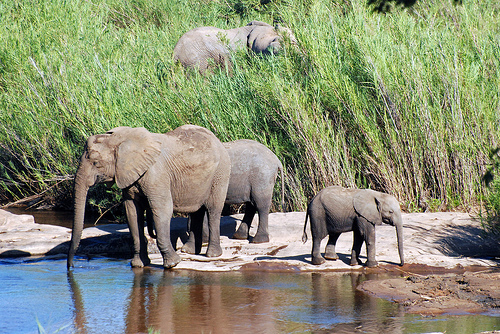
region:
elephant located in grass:
[165, 9, 307, 94]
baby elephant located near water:
[297, 183, 413, 273]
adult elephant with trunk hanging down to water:
[59, 115, 236, 274]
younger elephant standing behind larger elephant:
[176, 133, 291, 259]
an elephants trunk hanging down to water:
[59, 171, 99, 273]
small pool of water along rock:
[4, 263, 399, 330]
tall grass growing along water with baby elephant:
[298, 5, 498, 280]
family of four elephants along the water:
[60, 17, 414, 279]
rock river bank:
[0, 197, 499, 276]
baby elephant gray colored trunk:
[387, 218, 419, 271]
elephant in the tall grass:
[169, 18, 331, 94]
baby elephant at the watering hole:
[299, 150, 410, 271]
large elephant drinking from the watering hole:
[56, 118, 236, 269]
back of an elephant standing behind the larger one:
[214, 135, 281, 242]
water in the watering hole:
[30, 271, 127, 311]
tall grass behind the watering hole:
[339, 48, 445, 143]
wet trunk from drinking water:
[57, 223, 87, 285]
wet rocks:
[256, 240, 292, 257]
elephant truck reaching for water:
[66, 188, 80, 273]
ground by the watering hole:
[413, 219, 458, 259]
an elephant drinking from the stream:
[64, 126, 224, 275]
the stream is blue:
[0, 253, 156, 330]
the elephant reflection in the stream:
[49, 244, 329, 329]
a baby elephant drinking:
[285, 177, 412, 271]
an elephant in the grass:
[165, 11, 300, 74]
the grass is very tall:
[4, 1, 491, 206]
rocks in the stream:
[362, 257, 497, 322]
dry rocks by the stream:
[14, 202, 491, 274]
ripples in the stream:
[227, 275, 423, 327]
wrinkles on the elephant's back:
[152, 140, 190, 212]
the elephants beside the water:
[37, 113, 249, 270]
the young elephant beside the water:
[305, 172, 439, 268]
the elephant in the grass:
[156, 15, 328, 85]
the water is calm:
[34, 268, 281, 323]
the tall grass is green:
[299, 48, 472, 179]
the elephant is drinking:
[55, 107, 227, 269]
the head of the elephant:
[54, 118, 159, 268]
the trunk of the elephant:
[60, 188, 92, 273]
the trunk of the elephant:
[390, 220, 411, 270]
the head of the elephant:
[346, 182, 423, 271]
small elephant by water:
[307, 173, 438, 288]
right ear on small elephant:
[339, 180, 382, 226]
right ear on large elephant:
[111, 131, 152, 184]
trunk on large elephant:
[63, 168, 113, 274]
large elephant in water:
[33, 105, 257, 293]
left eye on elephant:
[88, 145, 103, 170]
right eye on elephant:
[380, 202, 407, 227]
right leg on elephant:
[300, 229, 338, 266]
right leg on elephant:
[359, 232, 382, 271]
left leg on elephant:
[157, 209, 184, 282]